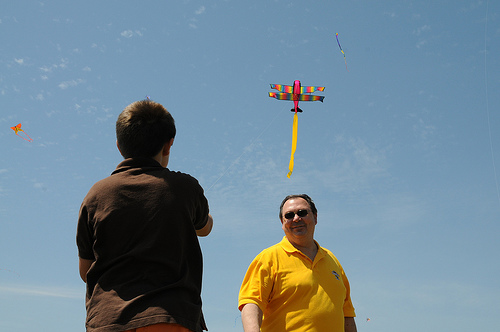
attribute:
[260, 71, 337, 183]
kite — colored, orange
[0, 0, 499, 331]
sky — blue, cloudy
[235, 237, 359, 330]
shirt — collared